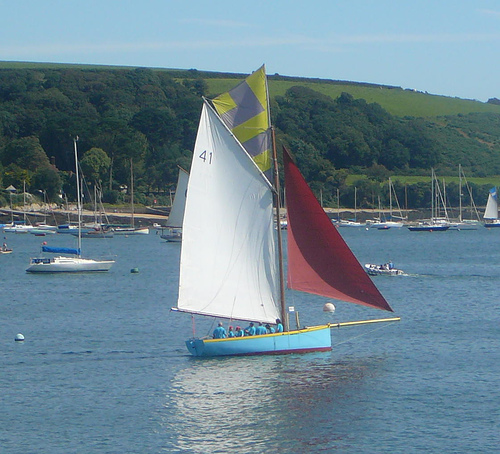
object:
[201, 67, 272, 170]
sail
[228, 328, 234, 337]
people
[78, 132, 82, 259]
pole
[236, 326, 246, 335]
people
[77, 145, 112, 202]
tree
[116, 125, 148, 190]
tree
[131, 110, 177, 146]
tree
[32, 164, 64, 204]
tree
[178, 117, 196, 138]
tree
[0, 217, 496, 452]
water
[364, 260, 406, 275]
motorboat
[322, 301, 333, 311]
buoy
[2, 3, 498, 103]
sky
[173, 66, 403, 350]
boat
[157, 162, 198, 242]
boat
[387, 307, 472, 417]
water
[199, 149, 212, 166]
41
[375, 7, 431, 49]
sky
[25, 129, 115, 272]
boat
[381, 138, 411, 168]
tree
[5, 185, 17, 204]
houses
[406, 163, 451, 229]
boat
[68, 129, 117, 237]
boat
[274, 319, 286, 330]
people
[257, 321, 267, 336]
people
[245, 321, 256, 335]
people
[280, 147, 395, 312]
red sail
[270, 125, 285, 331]
pole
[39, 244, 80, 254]
blue mast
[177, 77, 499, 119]
grass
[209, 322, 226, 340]
group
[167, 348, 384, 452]
reflection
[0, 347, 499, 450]
water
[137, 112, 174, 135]
leaves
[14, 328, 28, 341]
bobber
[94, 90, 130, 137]
tree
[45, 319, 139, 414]
water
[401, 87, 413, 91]
houses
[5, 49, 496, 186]
mountain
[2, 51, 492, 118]
top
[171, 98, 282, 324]
mast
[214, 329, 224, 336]
shirt